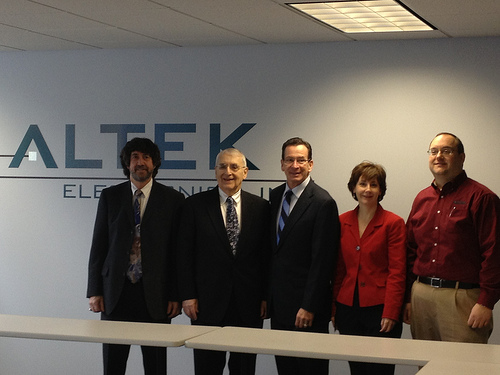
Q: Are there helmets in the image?
A: No, there are no helmets.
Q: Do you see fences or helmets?
A: No, there are no helmets or fences.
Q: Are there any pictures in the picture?
A: No, there are no pictures.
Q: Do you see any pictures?
A: No, there are no pictures.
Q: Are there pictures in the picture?
A: No, there are no pictures.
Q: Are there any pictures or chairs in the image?
A: No, there are no pictures or chairs.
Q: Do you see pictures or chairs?
A: No, there are no pictures or chairs.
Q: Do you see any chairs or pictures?
A: No, there are no pictures or chairs.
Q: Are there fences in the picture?
A: No, there are no fences.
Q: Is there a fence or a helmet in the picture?
A: No, there are no fences or helmets.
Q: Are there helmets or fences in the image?
A: No, there are no fences or helmets.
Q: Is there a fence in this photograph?
A: No, there are no fences.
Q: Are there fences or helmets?
A: No, there are no fences or helmets.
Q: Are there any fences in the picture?
A: No, there are no fences.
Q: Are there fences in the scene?
A: No, there are no fences.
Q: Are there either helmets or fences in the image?
A: No, there are no fences or helmets.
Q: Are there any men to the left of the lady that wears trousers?
A: Yes, there is a man to the left of the lady.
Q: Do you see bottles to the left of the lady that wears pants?
A: No, there is a man to the left of the lady.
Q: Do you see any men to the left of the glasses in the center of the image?
A: Yes, there is a man to the left of the glasses.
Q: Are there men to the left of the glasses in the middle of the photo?
A: Yes, there is a man to the left of the glasses.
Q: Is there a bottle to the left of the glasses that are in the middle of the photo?
A: No, there is a man to the left of the glasses.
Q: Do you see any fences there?
A: No, there are no fences.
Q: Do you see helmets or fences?
A: No, there are no fences or helmets.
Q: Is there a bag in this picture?
A: No, there are no bags.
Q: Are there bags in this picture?
A: No, there are no bags.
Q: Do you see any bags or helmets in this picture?
A: No, there are no bags or helmets.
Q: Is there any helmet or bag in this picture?
A: No, there are no bags or helmets.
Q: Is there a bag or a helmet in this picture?
A: No, there are no bags or helmets.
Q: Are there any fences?
A: No, there are no fences.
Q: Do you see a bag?
A: No, there are no bags.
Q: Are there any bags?
A: No, there are no bags.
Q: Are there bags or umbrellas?
A: No, there are no bags or umbrellas.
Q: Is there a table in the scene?
A: Yes, there is a table.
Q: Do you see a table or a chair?
A: Yes, there is a table.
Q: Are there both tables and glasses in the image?
A: Yes, there are both a table and glasses.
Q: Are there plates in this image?
A: No, there are no plates.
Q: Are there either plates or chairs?
A: No, there are no plates or chairs.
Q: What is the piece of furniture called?
A: The piece of furniture is a table.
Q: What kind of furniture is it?
A: The piece of furniture is a table.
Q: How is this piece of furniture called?
A: That is a table.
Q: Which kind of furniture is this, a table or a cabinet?
A: That is a table.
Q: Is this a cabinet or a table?
A: This is a table.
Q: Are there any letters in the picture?
A: Yes, there are letters.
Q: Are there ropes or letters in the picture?
A: Yes, there are letters.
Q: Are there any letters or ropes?
A: Yes, there are letters.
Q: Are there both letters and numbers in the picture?
A: No, there are letters but no numbers.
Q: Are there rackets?
A: No, there are no rackets.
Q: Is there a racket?
A: No, there are no rackets.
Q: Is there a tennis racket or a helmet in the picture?
A: No, there are no rackets or helmets.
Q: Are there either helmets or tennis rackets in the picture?
A: No, there are no tennis rackets or helmets.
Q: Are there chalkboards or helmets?
A: No, there are no helmets or chalkboards.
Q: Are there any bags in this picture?
A: No, there are no bags.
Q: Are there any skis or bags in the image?
A: No, there are no bags or skis.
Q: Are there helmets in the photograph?
A: No, there are no helmets.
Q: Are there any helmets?
A: No, there are no helmets.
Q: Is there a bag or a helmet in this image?
A: No, there are no helmets or bags.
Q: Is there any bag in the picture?
A: No, there are no bags.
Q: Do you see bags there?
A: No, there are no bags.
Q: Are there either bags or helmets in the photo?
A: No, there are no bags or helmets.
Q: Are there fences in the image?
A: No, there are no fences.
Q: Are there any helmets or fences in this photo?
A: No, there are no helmets or fences.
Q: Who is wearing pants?
A: The man is wearing pants.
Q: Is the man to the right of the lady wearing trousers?
A: Yes, the man is wearing trousers.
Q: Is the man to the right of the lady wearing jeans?
A: No, the man is wearing trousers.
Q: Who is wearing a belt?
A: The man is wearing a belt.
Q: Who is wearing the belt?
A: The man is wearing a belt.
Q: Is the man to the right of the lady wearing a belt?
A: Yes, the man is wearing a belt.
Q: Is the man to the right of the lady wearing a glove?
A: No, the man is wearing a belt.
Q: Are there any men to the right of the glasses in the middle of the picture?
A: Yes, there is a man to the right of the glasses.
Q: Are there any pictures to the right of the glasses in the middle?
A: No, there is a man to the right of the glasses.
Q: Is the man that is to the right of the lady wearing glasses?
A: Yes, the man is wearing glasses.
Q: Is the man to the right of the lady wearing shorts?
A: No, the man is wearing glasses.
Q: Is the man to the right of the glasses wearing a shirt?
A: Yes, the man is wearing a shirt.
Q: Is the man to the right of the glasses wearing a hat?
A: No, the man is wearing a shirt.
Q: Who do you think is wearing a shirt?
A: The man is wearing a shirt.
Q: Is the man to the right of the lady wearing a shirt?
A: Yes, the man is wearing a shirt.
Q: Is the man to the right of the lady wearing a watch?
A: No, the man is wearing a shirt.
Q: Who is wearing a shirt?
A: The man is wearing a shirt.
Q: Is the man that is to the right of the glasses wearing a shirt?
A: Yes, the man is wearing a shirt.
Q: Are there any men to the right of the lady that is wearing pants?
A: Yes, there is a man to the right of the lady.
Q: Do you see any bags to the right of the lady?
A: No, there is a man to the right of the lady.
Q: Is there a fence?
A: No, there are no fences.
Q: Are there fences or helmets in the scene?
A: No, there are no fences or helmets.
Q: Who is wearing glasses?
A: The man is wearing glasses.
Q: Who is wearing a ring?
A: The man is wearing a ring.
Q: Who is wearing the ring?
A: The man is wearing a ring.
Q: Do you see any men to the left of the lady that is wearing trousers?
A: Yes, there is a man to the left of the lady.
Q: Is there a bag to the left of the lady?
A: No, there is a man to the left of the lady.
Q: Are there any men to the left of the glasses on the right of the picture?
A: Yes, there is a man to the left of the glasses.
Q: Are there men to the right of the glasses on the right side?
A: No, the man is to the left of the glasses.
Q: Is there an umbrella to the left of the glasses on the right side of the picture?
A: No, there is a man to the left of the glasses.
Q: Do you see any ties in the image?
A: Yes, there is a tie.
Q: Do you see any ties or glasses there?
A: Yes, there is a tie.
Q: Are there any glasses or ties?
A: Yes, there is a tie.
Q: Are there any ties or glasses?
A: Yes, there is a tie.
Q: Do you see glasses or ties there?
A: Yes, there is a tie.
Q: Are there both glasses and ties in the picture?
A: Yes, there are both a tie and glasses.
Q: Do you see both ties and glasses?
A: Yes, there are both a tie and glasses.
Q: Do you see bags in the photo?
A: No, there are no bags.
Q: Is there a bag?
A: No, there are no bags.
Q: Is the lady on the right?
A: Yes, the lady is on the right of the image.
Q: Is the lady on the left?
A: No, the lady is on the right of the image.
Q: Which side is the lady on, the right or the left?
A: The lady is on the right of the image.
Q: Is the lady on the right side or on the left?
A: The lady is on the right of the image.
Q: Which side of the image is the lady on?
A: The lady is on the right of the image.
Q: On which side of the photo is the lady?
A: The lady is on the right of the image.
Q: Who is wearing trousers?
A: The lady is wearing trousers.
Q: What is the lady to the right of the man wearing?
A: The lady is wearing trousers.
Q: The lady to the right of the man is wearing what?
A: The lady is wearing trousers.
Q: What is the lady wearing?
A: The lady is wearing trousers.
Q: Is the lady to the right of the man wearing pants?
A: Yes, the lady is wearing pants.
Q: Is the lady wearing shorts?
A: No, the lady is wearing pants.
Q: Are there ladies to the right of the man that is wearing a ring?
A: Yes, there is a lady to the right of the man.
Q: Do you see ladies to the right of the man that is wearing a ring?
A: Yes, there is a lady to the right of the man.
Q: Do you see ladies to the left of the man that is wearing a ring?
A: No, the lady is to the right of the man.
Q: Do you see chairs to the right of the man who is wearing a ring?
A: No, there is a lady to the right of the man.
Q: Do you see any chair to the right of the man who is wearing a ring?
A: No, there is a lady to the right of the man.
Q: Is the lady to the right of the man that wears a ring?
A: Yes, the lady is to the right of the man.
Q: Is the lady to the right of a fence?
A: No, the lady is to the right of the man.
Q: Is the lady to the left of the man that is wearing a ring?
A: No, the lady is to the right of the man.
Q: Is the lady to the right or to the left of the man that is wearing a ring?
A: The lady is to the right of the man.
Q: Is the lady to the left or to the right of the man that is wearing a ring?
A: The lady is to the right of the man.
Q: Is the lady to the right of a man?
A: Yes, the lady is to the right of a man.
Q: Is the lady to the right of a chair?
A: No, the lady is to the right of a man.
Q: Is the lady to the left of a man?
A: No, the lady is to the right of a man.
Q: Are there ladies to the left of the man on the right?
A: Yes, there is a lady to the left of the man.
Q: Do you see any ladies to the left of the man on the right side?
A: Yes, there is a lady to the left of the man.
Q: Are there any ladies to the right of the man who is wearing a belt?
A: No, the lady is to the left of the man.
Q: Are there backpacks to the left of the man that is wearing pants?
A: No, there is a lady to the left of the man.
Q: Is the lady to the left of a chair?
A: No, the lady is to the left of a man.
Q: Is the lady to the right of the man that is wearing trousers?
A: No, the lady is to the left of the man.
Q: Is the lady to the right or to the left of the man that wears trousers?
A: The lady is to the left of the man.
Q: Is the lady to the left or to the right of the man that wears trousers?
A: The lady is to the left of the man.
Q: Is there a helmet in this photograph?
A: No, there are no helmets.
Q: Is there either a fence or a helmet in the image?
A: No, there are no helmets or fences.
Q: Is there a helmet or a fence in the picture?
A: No, there are no helmets or fences.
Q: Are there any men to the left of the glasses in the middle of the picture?
A: Yes, there is a man to the left of the glasses.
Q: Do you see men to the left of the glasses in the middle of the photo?
A: Yes, there is a man to the left of the glasses.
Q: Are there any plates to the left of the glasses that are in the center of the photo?
A: No, there is a man to the left of the glasses.